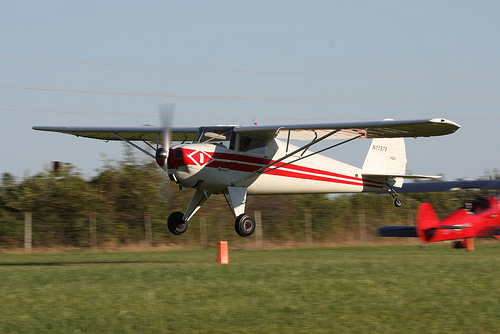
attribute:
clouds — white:
[29, 22, 111, 84]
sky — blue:
[1, 1, 498, 168]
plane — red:
[26, 81, 458, 271]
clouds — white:
[238, 65, 310, 109]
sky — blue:
[15, 15, 472, 126]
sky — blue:
[13, 4, 494, 104]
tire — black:
[231, 211, 258, 240]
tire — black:
[164, 208, 189, 236]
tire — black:
[392, 195, 404, 210]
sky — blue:
[2, 0, 497, 209]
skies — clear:
[65, 17, 465, 87]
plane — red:
[30, 108, 467, 264]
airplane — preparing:
[27, 116, 460, 236]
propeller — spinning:
[133, 105, 195, 200]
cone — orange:
[205, 234, 243, 279]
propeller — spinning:
[100, 105, 217, 210]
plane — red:
[376, 194, 497, 256]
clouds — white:
[1, 58, 71, 121]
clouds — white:
[111, 32, 234, 94]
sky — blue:
[2, 0, 497, 117]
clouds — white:
[111, 37, 207, 87]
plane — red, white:
[26, 104, 463, 237]